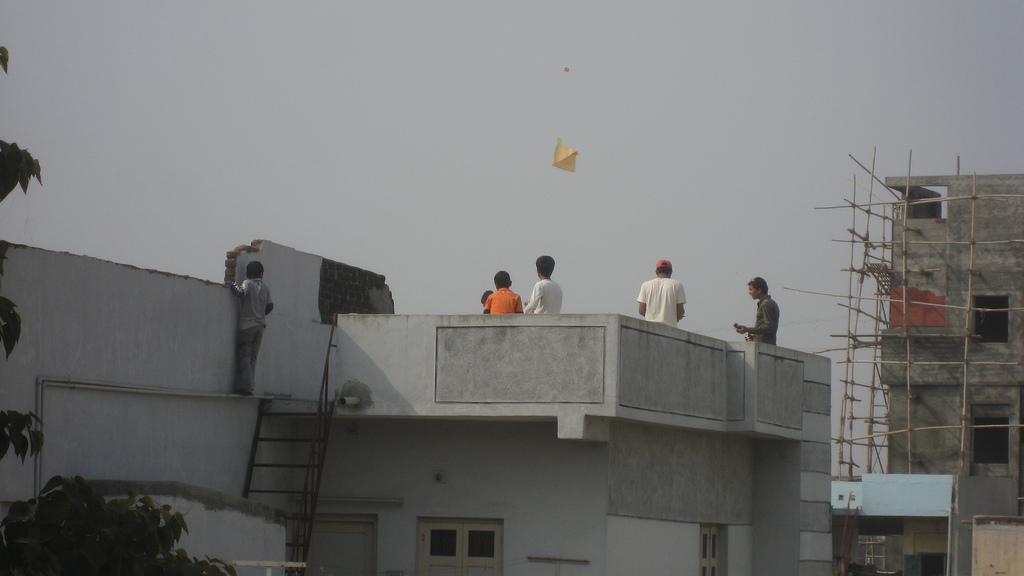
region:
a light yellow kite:
[545, 135, 591, 175]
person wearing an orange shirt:
[472, 264, 529, 318]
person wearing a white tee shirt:
[628, 255, 690, 332]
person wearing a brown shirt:
[728, 273, 793, 353]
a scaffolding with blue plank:
[814, 134, 1023, 564]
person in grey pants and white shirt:
[216, 252, 281, 401]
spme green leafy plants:
[1, 479, 264, 574]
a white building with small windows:
[10, 226, 849, 574]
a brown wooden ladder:
[242, 379, 344, 563]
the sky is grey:
[629, 84, 744, 162]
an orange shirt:
[489, 283, 521, 302]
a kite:
[546, 138, 589, 176]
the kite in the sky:
[551, 134, 580, 180]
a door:
[423, 514, 501, 562]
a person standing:
[237, 260, 280, 378]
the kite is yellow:
[538, 136, 589, 179]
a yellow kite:
[543, 143, 582, 189]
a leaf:
[0, 134, 43, 196]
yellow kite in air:
[527, 123, 592, 185]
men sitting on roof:
[481, 241, 579, 319]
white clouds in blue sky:
[320, 133, 384, 182]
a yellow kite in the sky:
[551, 130, 583, 170]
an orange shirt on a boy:
[481, 285, 521, 312]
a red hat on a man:
[652, 259, 669, 273]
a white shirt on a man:
[631, 269, 689, 317]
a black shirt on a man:
[741, 292, 786, 346]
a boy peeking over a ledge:
[227, 262, 276, 393]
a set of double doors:
[419, 509, 506, 570]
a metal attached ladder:
[236, 379, 331, 560]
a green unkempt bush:
[7, 474, 226, 573]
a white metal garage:
[603, 512, 711, 570]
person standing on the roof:
[626, 247, 690, 336]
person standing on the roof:
[735, 271, 790, 341]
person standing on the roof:
[525, 256, 563, 324]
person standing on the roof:
[477, 266, 531, 337]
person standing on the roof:
[220, 253, 285, 383]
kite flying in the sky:
[543, 129, 583, 180]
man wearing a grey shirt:
[733, 282, 790, 337]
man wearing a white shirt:
[629, 263, 687, 318]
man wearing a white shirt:
[518, 272, 567, 312]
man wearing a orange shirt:
[474, 278, 520, 317]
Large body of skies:
[125, 13, 332, 187]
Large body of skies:
[119, 41, 411, 188]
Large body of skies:
[129, 50, 389, 191]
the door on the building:
[422, 519, 521, 565]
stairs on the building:
[243, 404, 332, 525]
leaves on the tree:
[22, 484, 144, 564]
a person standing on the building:
[233, 256, 266, 377]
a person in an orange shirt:
[495, 269, 511, 320]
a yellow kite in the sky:
[547, 138, 583, 174]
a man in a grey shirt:
[740, 272, 778, 348]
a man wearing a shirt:
[234, 246, 280, 355]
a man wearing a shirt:
[483, 265, 519, 326]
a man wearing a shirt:
[522, 247, 571, 321]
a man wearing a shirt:
[632, 250, 689, 327]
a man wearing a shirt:
[729, 268, 786, 351]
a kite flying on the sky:
[531, 116, 601, 197]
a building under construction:
[844, 139, 1019, 485]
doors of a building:
[407, 508, 512, 570]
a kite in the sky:
[547, 138, 576, 170]